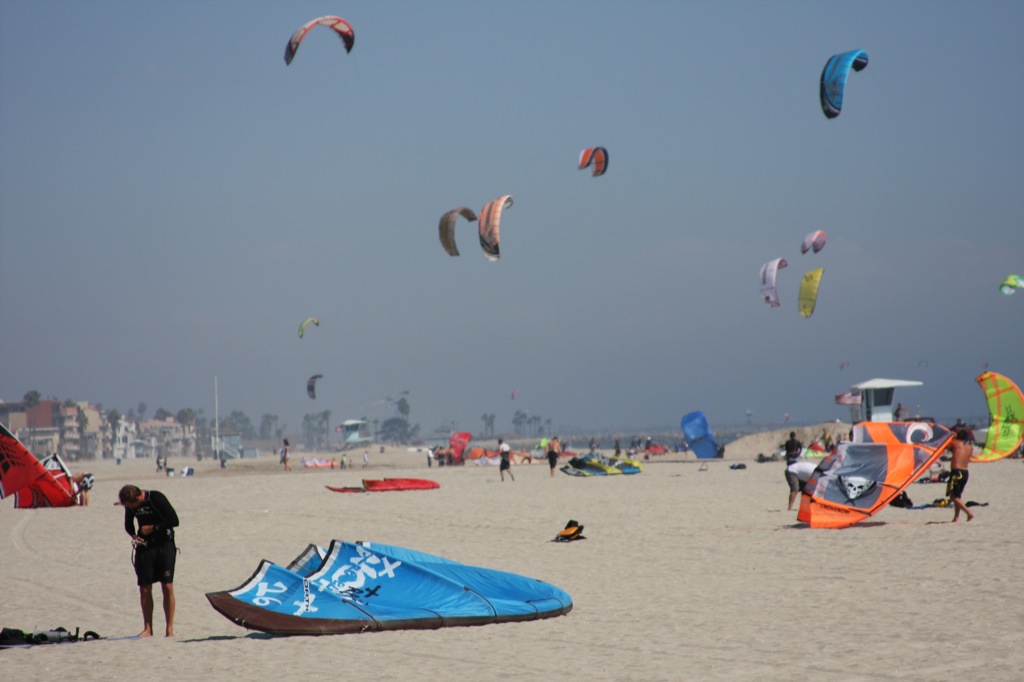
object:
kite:
[678, 408, 725, 460]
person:
[362, 450, 373, 468]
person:
[433, 445, 450, 467]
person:
[446, 442, 457, 466]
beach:
[464, 471, 871, 664]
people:
[424, 445, 437, 470]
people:
[278, 435, 294, 473]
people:
[496, 438, 518, 484]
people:
[783, 430, 804, 466]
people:
[783, 461, 826, 511]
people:
[543, 436, 563, 478]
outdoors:
[25, 29, 1022, 676]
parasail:
[436, 205, 480, 259]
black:
[137, 538, 164, 570]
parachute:
[202, 536, 579, 636]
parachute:
[322, 476, 442, 494]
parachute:
[793, 419, 958, 533]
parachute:
[560, 449, 647, 478]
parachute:
[442, 432, 476, 465]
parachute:
[0, 422, 97, 511]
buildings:
[0, 390, 224, 458]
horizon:
[17, 404, 1024, 458]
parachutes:
[756, 256, 789, 309]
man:
[118, 483, 183, 643]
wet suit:
[123, 489, 182, 586]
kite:
[816, 45, 868, 120]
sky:
[13, 10, 1021, 430]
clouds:
[0, 124, 289, 372]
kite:
[476, 193, 515, 262]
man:
[940, 423, 983, 522]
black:
[957, 480, 964, 487]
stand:
[849, 377, 924, 423]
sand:
[698, 535, 1024, 682]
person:
[339, 453, 348, 471]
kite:
[282, 13, 363, 71]